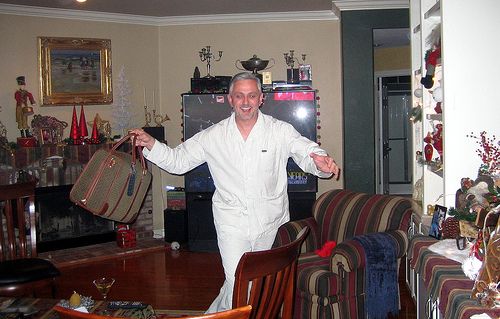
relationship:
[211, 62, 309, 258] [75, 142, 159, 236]
man holding suitcase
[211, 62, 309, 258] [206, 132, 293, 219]
man in robe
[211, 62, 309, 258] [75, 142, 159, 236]
man with suitcase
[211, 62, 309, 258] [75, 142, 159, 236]
man on suitcase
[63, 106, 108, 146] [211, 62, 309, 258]
trees near man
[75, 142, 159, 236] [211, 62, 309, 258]
suitcase near man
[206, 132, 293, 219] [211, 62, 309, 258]
robe on man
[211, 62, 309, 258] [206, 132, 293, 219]
man wearing robe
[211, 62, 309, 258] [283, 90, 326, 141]
man in front of tv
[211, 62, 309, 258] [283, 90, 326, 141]
man near tv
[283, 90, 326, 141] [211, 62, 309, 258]
tv near man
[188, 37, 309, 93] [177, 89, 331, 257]
candlesticks above tv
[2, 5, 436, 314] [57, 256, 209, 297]
living room has floor